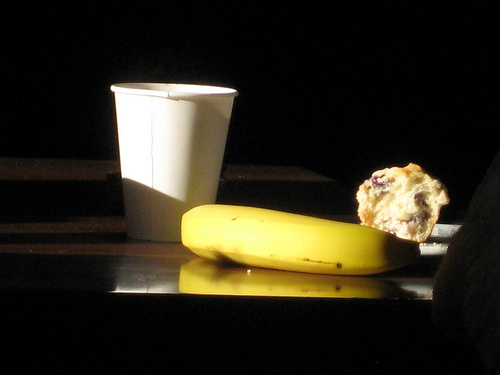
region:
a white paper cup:
[106, 77, 242, 246]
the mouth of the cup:
[106, 80, 241, 105]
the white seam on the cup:
[141, 92, 159, 246]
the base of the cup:
[117, 225, 199, 246]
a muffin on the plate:
[349, 156, 450, 250]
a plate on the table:
[390, 215, 472, 265]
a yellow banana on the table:
[176, 200, 430, 281]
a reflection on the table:
[171, 251, 405, 309]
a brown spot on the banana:
[331, 257, 348, 272]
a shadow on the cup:
[114, 171, 208, 251]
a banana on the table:
[176, 195, 430, 282]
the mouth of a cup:
[105, 73, 247, 116]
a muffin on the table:
[351, 155, 452, 246]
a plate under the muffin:
[394, 210, 476, 267]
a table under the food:
[2, 144, 481, 323]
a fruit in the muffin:
[368, 173, 394, 190]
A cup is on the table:
[103, 65, 251, 265]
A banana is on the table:
[168, 192, 429, 302]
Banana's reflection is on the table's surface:
[171, 253, 419, 320]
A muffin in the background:
[352, 149, 456, 249]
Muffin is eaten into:
[349, 148, 460, 258]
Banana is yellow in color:
[178, 191, 433, 295]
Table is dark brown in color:
[6, 151, 445, 325]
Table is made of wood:
[6, 146, 454, 325]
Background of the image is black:
[5, 9, 498, 149]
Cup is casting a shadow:
[3, 206, 158, 255]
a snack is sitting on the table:
[10, 8, 495, 355]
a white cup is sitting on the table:
[106, 74, 236, 244]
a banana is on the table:
[181, 194, 423, 281]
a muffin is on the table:
[350, 153, 452, 245]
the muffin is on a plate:
[350, 212, 470, 254]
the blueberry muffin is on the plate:
[349, 158, 459, 255]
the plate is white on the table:
[336, 216, 469, 260]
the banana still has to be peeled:
[179, 199, 423, 283]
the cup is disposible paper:
[103, 77, 240, 254]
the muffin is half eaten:
[349, 155, 449, 248]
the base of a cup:
[121, 216, 198, 248]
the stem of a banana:
[391, 232, 425, 270]